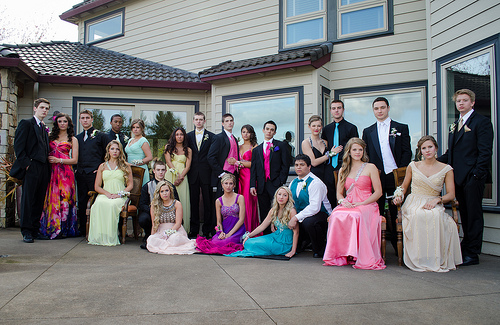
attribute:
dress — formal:
[407, 163, 462, 273]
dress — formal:
[325, 169, 384, 259]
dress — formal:
[247, 217, 302, 252]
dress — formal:
[203, 200, 248, 248]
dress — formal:
[88, 170, 127, 249]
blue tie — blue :
[323, 114, 353, 172]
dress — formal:
[403, 162, 461, 275]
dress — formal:
[327, 174, 388, 271]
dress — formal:
[237, 219, 297, 264]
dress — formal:
[199, 194, 244, 244]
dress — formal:
[145, 205, 201, 259]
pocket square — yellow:
[461, 125, 471, 132]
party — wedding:
[2, 85, 484, 268]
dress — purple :
[206, 176, 253, 256]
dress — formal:
[400, 159, 470, 273]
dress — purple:
[194, 190, 245, 256]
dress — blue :
[226, 204, 296, 259]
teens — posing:
[9, 57, 479, 268]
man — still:
[443, 83, 495, 268]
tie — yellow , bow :
[188, 126, 206, 136]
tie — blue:
[327, 122, 340, 169]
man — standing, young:
[433, 85, 493, 268]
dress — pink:
[323, 171, 387, 267]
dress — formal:
[90, 165, 134, 253]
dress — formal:
[150, 199, 192, 251]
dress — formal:
[207, 196, 253, 255]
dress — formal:
[245, 207, 295, 260]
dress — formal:
[326, 170, 386, 264]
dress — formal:
[398, 159, 461, 279]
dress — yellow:
[93, 160, 128, 254]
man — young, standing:
[6, 94, 61, 236]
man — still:
[352, 98, 417, 216]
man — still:
[320, 91, 357, 187]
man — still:
[272, 146, 331, 246]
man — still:
[247, 120, 292, 210]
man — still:
[215, 109, 237, 199]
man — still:
[184, 106, 218, 216]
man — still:
[139, 160, 179, 202]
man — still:
[106, 110, 128, 159]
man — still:
[70, 105, 101, 191]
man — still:
[3, 92, 61, 216]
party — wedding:
[10, 77, 490, 278]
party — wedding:
[18, 80, 489, 300]